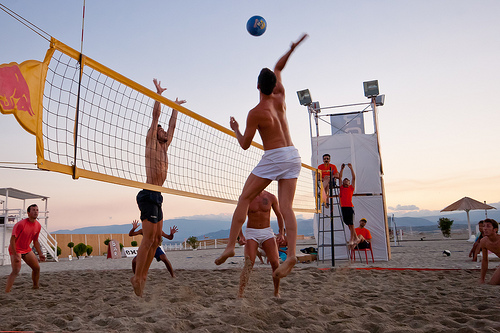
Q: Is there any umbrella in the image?
A: Yes, there is an umbrella.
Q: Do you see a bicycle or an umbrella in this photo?
A: Yes, there is an umbrella.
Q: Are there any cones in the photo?
A: No, there are no cones.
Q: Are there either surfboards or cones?
A: No, there are no cones or surfboards.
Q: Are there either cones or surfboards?
A: No, there are no cones or surfboards.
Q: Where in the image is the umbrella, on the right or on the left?
A: The umbrella is on the right of the image.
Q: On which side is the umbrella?
A: The umbrella is on the right of the image.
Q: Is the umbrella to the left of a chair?
A: No, the umbrella is to the right of a chair.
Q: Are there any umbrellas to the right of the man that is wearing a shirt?
A: Yes, there is an umbrella to the right of the man.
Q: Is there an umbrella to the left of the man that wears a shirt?
A: No, the umbrella is to the right of the man.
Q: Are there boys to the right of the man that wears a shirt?
A: No, there is an umbrella to the right of the man.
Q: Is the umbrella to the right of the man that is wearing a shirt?
A: Yes, the umbrella is to the right of the man.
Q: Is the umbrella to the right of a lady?
A: No, the umbrella is to the right of the man.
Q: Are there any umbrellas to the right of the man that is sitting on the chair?
A: Yes, there is an umbrella to the right of the man.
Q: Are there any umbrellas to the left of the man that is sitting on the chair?
A: No, the umbrella is to the right of the man.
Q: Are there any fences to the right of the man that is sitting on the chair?
A: No, there is an umbrella to the right of the man.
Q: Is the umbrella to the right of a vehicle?
A: No, the umbrella is to the right of a man.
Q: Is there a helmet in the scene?
A: No, there are no helmets.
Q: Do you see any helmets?
A: No, there are no helmets.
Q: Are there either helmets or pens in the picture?
A: No, there are no helmets or pens.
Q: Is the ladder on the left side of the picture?
A: Yes, the ladder is on the left of the image.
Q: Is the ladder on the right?
A: No, the ladder is on the left of the image.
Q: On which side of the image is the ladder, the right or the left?
A: The ladder is on the left of the image.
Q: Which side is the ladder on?
A: The ladder is on the left of the image.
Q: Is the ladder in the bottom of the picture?
A: Yes, the ladder is in the bottom of the image.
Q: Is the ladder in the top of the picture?
A: No, the ladder is in the bottom of the image.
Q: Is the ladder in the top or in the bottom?
A: The ladder is in the bottom of the image.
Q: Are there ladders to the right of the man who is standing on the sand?
A: Yes, there is a ladder to the right of the man.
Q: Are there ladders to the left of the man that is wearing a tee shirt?
A: No, the ladder is to the right of the man.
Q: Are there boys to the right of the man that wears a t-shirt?
A: No, there is a ladder to the right of the man.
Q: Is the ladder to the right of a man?
A: Yes, the ladder is to the right of a man.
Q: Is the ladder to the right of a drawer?
A: No, the ladder is to the right of a man.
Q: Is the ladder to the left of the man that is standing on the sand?
A: No, the ladder is to the right of the man.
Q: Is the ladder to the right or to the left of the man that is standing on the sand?
A: The ladder is to the right of the man.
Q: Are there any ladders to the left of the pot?
A: Yes, there is a ladder to the left of the pot.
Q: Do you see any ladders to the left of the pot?
A: Yes, there is a ladder to the left of the pot.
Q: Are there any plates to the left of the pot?
A: No, there is a ladder to the left of the pot.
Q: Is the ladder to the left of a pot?
A: Yes, the ladder is to the left of a pot.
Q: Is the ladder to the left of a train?
A: No, the ladder is to the left of a pot.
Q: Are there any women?
A: No, there are no women.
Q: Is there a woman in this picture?
A: No, there are no women.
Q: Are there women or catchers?
A: No, there are no women or catchers.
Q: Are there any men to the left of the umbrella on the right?
A: Yes, there is a man to the left of the umbrella.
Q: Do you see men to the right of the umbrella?
A: No, the man is to the left of the umbrella.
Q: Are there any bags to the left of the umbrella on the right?
A: No, there is a man to the left of the umbrella.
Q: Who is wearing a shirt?
A: The man is wearing a shirt.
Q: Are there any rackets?
A: No, there are no rackets.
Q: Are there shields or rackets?
A: No, there are no rackets or shields.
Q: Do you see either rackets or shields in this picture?
A: No, there are no rackets or shields.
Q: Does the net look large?
A: Yes, the net is large.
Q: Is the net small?
A: No, the net is large.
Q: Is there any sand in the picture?
A: Yes, there is sand.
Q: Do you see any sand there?
A: Yes, there is sand.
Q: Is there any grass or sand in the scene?
A: Yes, there is sand.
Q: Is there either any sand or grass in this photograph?
A: Yes, there is sand.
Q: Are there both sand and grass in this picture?
A: No, there is sand but no grass.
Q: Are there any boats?
A: No, there are no boats.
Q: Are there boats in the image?
A: No, there are no boats.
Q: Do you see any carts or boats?
A: No, there are no boats or carts.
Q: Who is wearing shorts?
A: The man is wearing shorts.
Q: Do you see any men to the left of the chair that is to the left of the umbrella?
A: Yes, there is a man to the left of the chair.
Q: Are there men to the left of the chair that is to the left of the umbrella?
A: Yes, there is a man to the left of the chair.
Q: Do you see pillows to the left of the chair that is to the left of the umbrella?
A: No, there is a man to the left of the chair.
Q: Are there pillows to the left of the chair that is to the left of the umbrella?
A: No, there is a man to the left of the chair.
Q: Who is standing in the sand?
A: The man is standing in the sand.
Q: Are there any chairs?
A: Yes, there is a chair.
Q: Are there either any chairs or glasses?
A: Yes, there is a chair.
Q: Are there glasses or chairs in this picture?
A: Yes, there is a chair.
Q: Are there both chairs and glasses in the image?
A: No, there is a chair but no glasses.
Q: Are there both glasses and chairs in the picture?
A: No, there is a chair but no glasses.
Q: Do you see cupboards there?
A: No, there are no cupboards.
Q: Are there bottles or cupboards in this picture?
A: No, there are no cupboards or bottles.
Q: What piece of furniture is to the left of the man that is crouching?
A: The piece of furniture is a chair.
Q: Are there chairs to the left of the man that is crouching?
A: Yes, there is a chair to the left of the man.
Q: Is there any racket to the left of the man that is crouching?
A: No, there is a chair to the left of the man.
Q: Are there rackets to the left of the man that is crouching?
A: No, there is a chair to the left of the man.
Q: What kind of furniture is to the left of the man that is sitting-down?
A: The piece of furniture is a chair.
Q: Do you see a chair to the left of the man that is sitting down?
A: Yes, there is a chair to the left of the man.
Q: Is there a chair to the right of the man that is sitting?
A: No, the chair is to the left of the man.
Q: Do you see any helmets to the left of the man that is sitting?
A: No, there is a chair to the left of the man.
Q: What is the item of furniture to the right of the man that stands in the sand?
A: The piece of furniture is a chair.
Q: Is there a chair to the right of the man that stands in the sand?
A: Yes, there is a chair to the right of the man.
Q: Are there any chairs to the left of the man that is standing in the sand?
A: No, the chair is to the right of the man.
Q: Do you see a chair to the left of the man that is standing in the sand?
A: No, the chair is to the right of the man.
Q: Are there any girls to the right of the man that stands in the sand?
A: No, there is a chair to the right of the man.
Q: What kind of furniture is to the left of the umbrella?
A: The piece of furniture is a chair.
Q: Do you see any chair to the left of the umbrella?
A: Yes, there is a chair to the left of the umbrella.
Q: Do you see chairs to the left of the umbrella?
A: Yes, there is a chair to the left of the umbrella.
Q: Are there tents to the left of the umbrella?
A: No, there is a chair to the left of the umbrella.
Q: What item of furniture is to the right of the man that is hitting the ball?
A: The piece of furniture is a chair.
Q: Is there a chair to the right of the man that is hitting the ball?
A: Yes, there is a chair to the right of the man.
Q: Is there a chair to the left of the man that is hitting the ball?
A: No, the chair is to the right of the man.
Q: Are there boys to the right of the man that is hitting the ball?
A: No, there is a chair to the right of the man.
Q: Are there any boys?
A: No, there are no boys.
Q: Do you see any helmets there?
A: No, there are no helmets.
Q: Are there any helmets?
A: No, there are no helmets.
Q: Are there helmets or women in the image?
A: No, there are no helmets or women.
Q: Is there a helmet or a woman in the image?
A: No, there are no helmets or women.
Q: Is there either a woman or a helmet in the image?
A: No, there are no helmets or women.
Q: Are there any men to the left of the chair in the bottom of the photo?
A: Yes, there is a man to the left of the chair.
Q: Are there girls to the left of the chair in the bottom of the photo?
A: No, there is a man to the left of the chair.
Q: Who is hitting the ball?
A: The man is hitting the ball.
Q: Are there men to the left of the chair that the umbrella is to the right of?
A: Yes, there is a man to the left of the chair.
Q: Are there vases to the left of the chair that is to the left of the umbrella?
A: No, there is a man to the left of the chair.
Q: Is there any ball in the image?
A: Yes, there is a ball.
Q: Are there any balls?
A: Yes, there is a ball.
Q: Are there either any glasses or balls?
A: Yes, there is a ball.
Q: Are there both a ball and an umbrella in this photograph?
A: Yes, there are both a ball and an umbrella.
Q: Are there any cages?
A: No, there are no cages.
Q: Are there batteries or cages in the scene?
A: No, there are no cages or batteries.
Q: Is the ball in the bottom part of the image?
A: No, the ball is in the top of the image.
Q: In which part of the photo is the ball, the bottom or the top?
A: The ball is in the top of the image.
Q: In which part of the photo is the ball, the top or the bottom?
A: The ball is in the top of the image.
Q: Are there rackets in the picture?
A: No, there are no rackets.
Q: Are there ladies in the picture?
A: No, there are no ladies.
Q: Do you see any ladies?
A: No, there are no ladies.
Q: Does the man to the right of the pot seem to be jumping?
A: Yes, the man is jumping.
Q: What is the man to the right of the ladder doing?
A: The man is jumping.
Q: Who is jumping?
A: The man is jumping.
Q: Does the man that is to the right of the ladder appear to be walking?
A: No, the man is jumping.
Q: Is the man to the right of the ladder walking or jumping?
A: The man is jumping.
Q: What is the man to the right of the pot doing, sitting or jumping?
A: The man is jumping.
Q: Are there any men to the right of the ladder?
A: Yes, there is a man to the right of the ladder.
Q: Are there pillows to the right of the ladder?
A: No, there is a man to the right of the ladder.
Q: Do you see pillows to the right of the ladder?
A: No, there is a man to the right of the ladder.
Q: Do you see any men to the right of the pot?
A: Yes, there is a man to the right of the pot.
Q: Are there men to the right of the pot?
A: Yes, there is a man to the right of the pot.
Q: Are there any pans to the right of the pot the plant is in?
A: No, there is a man to the right of the pot.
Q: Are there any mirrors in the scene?
A: No, there are no mirrors.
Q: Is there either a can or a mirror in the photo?
A: No, there are no mirrors or cans.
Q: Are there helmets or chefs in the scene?
A: No, there are no helmets or chefs.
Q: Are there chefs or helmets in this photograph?
A: No, there are no helmets or chefs.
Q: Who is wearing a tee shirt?
A: The man is wearing a tee shirt.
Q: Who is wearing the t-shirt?
A: The man is wearing a tee shirt.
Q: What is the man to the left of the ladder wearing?
A: The man is wearing a tee shirt.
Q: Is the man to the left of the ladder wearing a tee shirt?
A: Yes, the man is wearing a tee shirt.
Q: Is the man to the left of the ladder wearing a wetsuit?
A: No, the man is wearing a tee shirt.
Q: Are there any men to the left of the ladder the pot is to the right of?
A: Yes, there is a man to the left of the ladder.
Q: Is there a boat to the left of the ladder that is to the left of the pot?
A: No, there is a man to the left of the ladder.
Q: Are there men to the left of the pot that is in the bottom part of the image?
A: Yes, there is a man to the left of the pot.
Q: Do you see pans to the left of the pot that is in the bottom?
A: No, there is a man to the left of the pot.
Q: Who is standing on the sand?
A: The man is standing on the sand.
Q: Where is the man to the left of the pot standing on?
A: The man is standing on the sand.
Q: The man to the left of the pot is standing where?
A: The man is standing on the sand.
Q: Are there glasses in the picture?
A: No, there are no glasses.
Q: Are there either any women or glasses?
A: No, there are no glasses or women.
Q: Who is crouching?
A: The man is crouching.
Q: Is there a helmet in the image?
A: No, there are no helmets.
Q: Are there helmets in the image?
A: No, there are no helmets.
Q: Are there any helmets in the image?
A: No, there are no helmets.